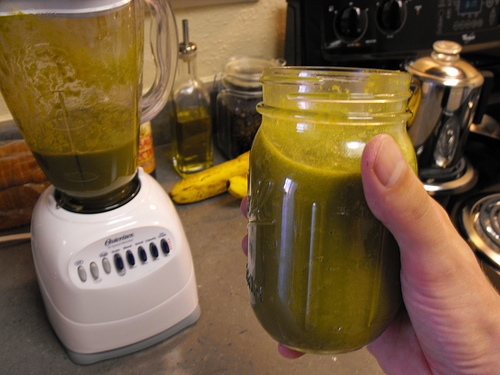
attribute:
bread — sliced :
[2, 140, 28, 232]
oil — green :
[179, 105, 216, 171]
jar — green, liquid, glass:
[247, 68, 422, 356]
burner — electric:
[456, 185, 498, 269]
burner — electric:
[410, 162, 481, 192]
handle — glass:
[138, 1, 187, 133]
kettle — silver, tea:
[404, 46, 486, 223]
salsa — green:
[248, 132, 417, 352]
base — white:
[29, 186, 200, 364]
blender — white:
[0, 2, 203, 367]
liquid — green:
[248, 129, 418, 353]